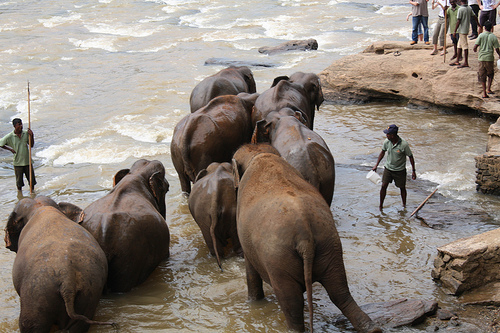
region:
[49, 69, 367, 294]
pack of brown elephants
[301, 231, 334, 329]
elephant has brown tail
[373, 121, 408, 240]
man next to elephant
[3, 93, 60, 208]
man is holding brown pole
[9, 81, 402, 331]
elephants in water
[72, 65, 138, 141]
water is brown and choppy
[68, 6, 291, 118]
waves form in water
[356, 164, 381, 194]
man is holding bucket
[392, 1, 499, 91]
people standing on shore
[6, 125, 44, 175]
man has green shirt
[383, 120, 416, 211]
Person standing water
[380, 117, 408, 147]
Man wearing a hat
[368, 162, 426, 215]
Man wearing shorts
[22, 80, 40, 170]
Man holding a stick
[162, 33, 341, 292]
Elephants walking in water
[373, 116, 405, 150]
Man looking at elephants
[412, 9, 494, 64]
People standing on a ledge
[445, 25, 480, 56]
Man wearing brown shorts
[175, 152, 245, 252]
Baby elephant walking in water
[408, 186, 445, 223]
Stick in the water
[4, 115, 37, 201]
a man holding a pole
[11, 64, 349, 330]
a group of elephants in the water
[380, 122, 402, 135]
a blue cap on a man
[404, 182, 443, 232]
a pole in the water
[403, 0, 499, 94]
a group of people on a rock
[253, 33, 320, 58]
a rock in the water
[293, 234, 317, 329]
the tail of an elephant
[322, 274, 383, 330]
the leg of an elephant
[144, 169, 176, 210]
an elephant ear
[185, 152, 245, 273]
a baby elephant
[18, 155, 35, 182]
part of a stick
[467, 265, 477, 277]
edge of a wall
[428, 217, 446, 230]
part of a river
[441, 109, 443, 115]
edge of a lake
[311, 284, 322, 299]
tail of an elephant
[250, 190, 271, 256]
body of an elephant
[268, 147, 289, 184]
back of an elephant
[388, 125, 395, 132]
head of a man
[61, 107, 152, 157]
small waves in the water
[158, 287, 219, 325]
brown muddy water in the river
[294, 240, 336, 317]
skinny tail on elephant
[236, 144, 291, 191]
hump on elephant's back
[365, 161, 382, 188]
white jug in man's hand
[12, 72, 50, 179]
man holding stick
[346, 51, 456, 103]
large brown rock on shore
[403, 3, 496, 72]
people standing on the shore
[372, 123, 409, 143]
cap on man's head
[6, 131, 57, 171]
short sleeve green shirt